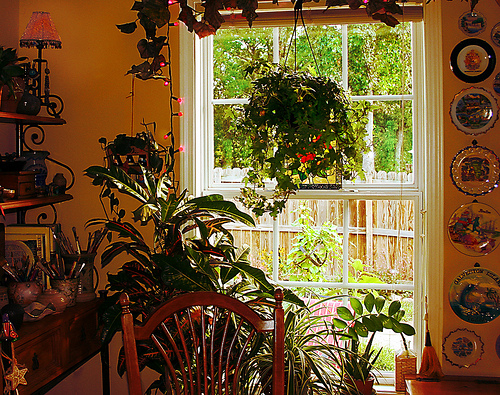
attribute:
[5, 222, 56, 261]
frame — picture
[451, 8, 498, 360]
plates — decorative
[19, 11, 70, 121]
holder — light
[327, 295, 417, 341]
leaves — green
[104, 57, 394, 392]
plants — green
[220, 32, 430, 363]
door — clear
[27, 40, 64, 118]
base — black, iron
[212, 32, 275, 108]
window — clear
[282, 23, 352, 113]
window — clear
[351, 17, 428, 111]
window — clear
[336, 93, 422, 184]
window — clear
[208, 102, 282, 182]
window — clear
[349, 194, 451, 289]
window — clear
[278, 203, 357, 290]
window — clear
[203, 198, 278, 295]
window — clear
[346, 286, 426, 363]
window — clear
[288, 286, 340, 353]
window — clear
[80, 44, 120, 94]
wall — yellow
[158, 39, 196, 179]
lights — stringed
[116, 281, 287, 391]
chair — wood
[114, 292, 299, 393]
back — brown, wood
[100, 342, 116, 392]
leg — black, metal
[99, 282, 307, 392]
chair — dark brown